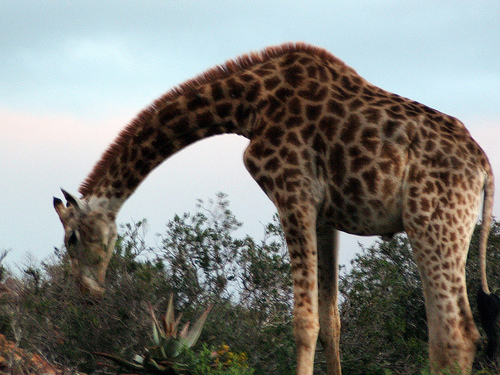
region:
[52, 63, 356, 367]
the giraffe is bent over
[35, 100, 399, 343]
this is a giraffe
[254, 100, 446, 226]
the giraffe is spotted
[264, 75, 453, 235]
the giraffe is brown and tan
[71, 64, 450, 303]
this giraffe is grazing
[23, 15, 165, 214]
the sky is white and gray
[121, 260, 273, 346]
this is a bunch of foilage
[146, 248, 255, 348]
the foilage is brown and green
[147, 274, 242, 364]
this plant is white and pink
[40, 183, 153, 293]
head of the animal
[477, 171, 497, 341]
tail of the animal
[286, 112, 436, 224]
brown and white body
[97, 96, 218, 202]
neck of the giraffe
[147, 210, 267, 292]
branches in the distance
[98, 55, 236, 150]
hair on back of giraffe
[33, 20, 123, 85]
blue sky above land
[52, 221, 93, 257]
eye of the giraffe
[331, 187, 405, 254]
bottom of the giraffe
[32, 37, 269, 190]
giraffe has brown mane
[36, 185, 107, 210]
giraffe has brown ears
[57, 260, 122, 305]
giraffe has brown nose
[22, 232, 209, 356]
giraffe eats green plants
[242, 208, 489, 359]
brown and white legs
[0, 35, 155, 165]
blue and white sky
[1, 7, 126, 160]
thick layers of clouds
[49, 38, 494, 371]
giraffe bending over to eat something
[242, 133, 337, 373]
front legs of the giraffe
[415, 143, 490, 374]
hind legs of the giraffe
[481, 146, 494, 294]
tail of the giraffe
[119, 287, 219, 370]
pointed plant on the ground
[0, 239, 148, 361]
bush that the giraffe is eating from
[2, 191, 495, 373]
shrubs and trees in the background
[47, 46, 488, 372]
a giraffe is eating something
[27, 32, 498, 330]
brown giraffe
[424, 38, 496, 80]
white clouds in blue sky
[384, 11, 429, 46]
white clouds in blue sky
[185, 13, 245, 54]
white clouds in blue sky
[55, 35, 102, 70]
white clouds in blue sky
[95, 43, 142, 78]
white clouds in blue sky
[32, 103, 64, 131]
white clouds in blue sky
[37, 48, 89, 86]
white clouds in blue sky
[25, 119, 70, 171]
white clouds in blue sky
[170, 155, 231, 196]
white clouds in blue sky